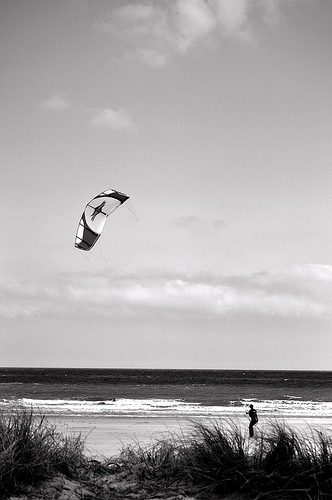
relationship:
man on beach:
[241, 402, 261, 440] [3, 353, 331, 487]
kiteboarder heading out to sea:
[70, 185, 134, 259] [8, 362, 331, 429]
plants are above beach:
[4, 431, 331, 499] [3, 353, 331, 487]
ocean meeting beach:
[8, 362, 331, 429] [3, 353, 331, 487]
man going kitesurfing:
[241, 402, 261, 440] [70, 189, 260, 442]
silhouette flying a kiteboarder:
[241, 402, 261, 440] [74, 188, 131, 252]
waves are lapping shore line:
[7, 396, 331, 414] [9, 409, 331, 431]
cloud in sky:
[150, 3, 227, 50] [9, 1, 327, 228]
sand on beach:
[41, 413, 331, 448] [3, 353, 331, 487]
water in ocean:
[8, 362, 331, 429] [3, 353, 331, 487]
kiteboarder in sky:
[74, 188, 131, 252] [9, 1, 327, 228]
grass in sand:
[4, 410, 331, 498] [41, 413, 331, 448]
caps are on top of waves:
[37, 396, 190, 409] [7, 396, 331, 414]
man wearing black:
[246, 404, 259, 437] [250, 409, 258, 434]